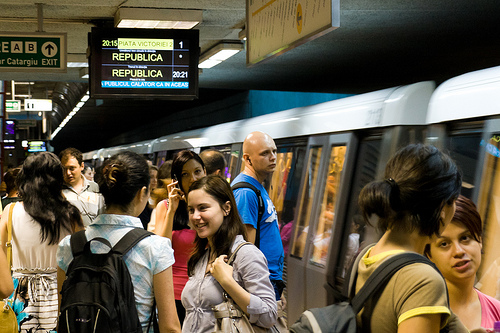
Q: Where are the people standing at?
A: A subway platform.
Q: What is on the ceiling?
A: A sign showing the exit.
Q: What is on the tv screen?
A: The time for the trains.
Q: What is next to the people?
A: The subway train.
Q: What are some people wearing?
A: Backpacks.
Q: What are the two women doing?
A: Talking.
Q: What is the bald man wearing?
A: A blue shirt.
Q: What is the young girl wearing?
A: Black backpack.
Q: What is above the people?
A: A screen showing the time for the trains.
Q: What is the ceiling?
A: Above everything.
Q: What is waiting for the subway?
A: The crowd of people.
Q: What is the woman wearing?
A: The black backpack.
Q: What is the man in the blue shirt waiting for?
A: The train.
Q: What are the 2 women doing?
A: Talking.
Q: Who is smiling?
A: Woman in grey.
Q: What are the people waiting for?
A: Train.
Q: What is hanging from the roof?
A: Train schedule.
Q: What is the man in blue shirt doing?
A: Waiting.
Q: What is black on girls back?
A: Back pack.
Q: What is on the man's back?
A: Backpack.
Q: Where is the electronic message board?
A: Above the tracks.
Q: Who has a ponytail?
A: A woman.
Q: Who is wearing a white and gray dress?
A: A woman.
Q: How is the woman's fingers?
A: Crossed.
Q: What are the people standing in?
A: Train station.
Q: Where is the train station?
A: Subway.